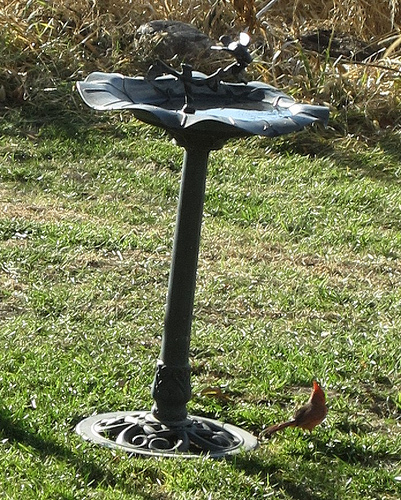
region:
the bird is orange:
[271, 347, 331, 447]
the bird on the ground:
[264, 346, 343, 481]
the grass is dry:
[259, 19, 340, 83]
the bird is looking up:
[290, 371, 350, 480]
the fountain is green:
[103, 70, 255, 436]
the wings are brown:
[297, 397, 329, 430]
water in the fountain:
[187, 94, 271, 135]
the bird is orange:
[282, 370, 318, 440]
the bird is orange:
[286, 354, 362, 451]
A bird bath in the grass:
[42, 11, 366, 493]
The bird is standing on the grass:
[258, 373, 330, 445]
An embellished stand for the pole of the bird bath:
[41, 359, 261, 458]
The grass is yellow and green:
[219, 170, 389, 376]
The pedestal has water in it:
[66, 64, 334, 140]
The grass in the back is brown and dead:
[4, 6, 73, 106]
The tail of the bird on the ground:
[250, 410, 302, 441]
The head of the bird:
[305, 376, 330, 405]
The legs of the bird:
[295, 425, 318, 437]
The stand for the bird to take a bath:
[137, 40, 264, 94]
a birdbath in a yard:
[65, 21, 302, 479]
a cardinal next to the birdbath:
[265, 365, 333, 447]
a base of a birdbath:
[74, 365, 269, 460]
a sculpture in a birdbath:
[129, 16, 280, 109]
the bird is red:
[253, 357, 357, 452]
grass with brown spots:
[5, 223, 359, 495]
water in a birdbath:
[164, 90, 283, 120]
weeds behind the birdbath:
[269, 2, 396, 101]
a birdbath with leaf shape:
[67, 43, 356, 164]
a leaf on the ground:
[202, 367, 230, 404]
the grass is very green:
[232, 253, 386, 370]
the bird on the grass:
[288, 379, 336, 427]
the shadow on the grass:
[10, 418, 77, 461]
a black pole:
[167, 177, 209, 329]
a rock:
[131, 18, 220, 55]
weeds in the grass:
[314, 50, 397, 107]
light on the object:
[284, 97, 312, 123]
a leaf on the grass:
[199, 373, 233, 404]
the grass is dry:
[233, 237, 349, 284]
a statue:
[211, 39, 259, 75]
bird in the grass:
[248, 373, 333, 450]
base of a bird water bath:
[68, 400, 271, 460]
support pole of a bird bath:
[139, 139, 219, 427]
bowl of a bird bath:
[69, 69, 330, 146]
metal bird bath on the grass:
[30, 24, 335, 465]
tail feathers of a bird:
[251, 415, 299, 439]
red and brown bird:
[253, 373, 334, 456]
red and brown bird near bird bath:
[258, 375, 339, 452]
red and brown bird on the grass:
[251, 374, 337, 453]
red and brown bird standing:
[246, 375, 337, 454]